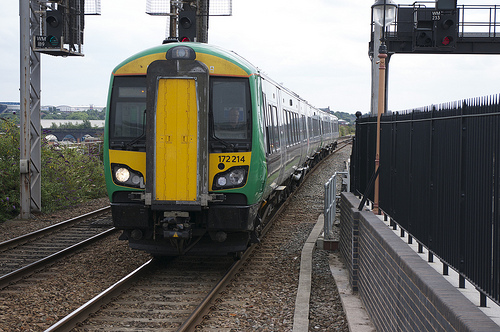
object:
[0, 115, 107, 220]
bushes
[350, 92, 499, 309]
fence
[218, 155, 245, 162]
number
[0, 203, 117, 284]
track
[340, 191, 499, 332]
wall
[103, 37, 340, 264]
train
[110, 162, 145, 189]
headlight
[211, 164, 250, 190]
headlight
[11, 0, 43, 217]
pole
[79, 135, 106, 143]
roof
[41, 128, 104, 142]
building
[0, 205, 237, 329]
two tracks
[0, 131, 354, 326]
ground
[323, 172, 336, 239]
gate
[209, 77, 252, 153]
window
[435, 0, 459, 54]
traffic light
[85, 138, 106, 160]
buildings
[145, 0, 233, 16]
lights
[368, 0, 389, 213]
pole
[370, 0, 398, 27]
lights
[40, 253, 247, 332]
track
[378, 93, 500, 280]
fence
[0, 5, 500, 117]
sky